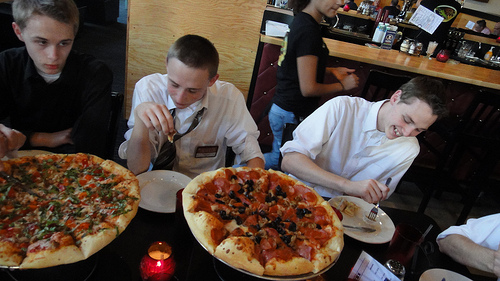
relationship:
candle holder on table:
[138, 241, 176, 278] [1, 170, 348, 272]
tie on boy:
[151, 107, 204, 171] [118, 34, 264, 176]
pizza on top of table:
[0, 149, 140, 269] [1, 161, 468, 279]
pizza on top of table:
[181, 167, 344, 276] [1, 161, 468, 279]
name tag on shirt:
[188, 141, 225, 160] [116, 65, 273, 175]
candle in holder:
[139, 240, 176, 280] [137, 239, 177, 279]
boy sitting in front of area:
[0, 9, 121, 160] [0, 5, 128, 146]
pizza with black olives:
[183, 166, 345, 274] [217, 172, 317, 252]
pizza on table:
[0, 147, 140, 266] [0, 196, 472, 279]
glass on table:
[386, 224, 424, 264] [19, 152, 442, 279]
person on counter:
[232, 0, 360, 170] [331, 45, 497, 82]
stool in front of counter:
[424, 85, 497, 227] [261, 27, 498, 91]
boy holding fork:
[279, 77, 449, 204] [368, 175, 395, 221]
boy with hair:
[279, 77, 449, 204] [164, 33, 219, 83]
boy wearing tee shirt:
[0, 0, 112, 159] [0, 49, 158, 146]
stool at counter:
[416, 90, 500, 226] [321, 38, 500, 90]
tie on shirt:
[150, 100, 213, 178] [119, 89, 252, 192]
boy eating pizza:
[0, 0, 112, 159] [183, 166, 345, 274]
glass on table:
[378, 206, 435, 277] [81, 202, 478, 277]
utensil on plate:
[340, 219, 377, 235] [324, 192, 400, 243]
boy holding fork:
[279, 77, 449, 204] [364, 176, 392, 236]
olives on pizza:
[221, 179, 332, 244] [183, 166, 345, 274]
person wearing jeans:
[232, 0, 360, 170] [261, 107, 291, 173]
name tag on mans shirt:
[194, 146, 218, 159] [115, 70, 267, 178]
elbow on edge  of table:
[433, 212, 472, 269] [57, 149, 437, 269]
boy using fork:
[280, 71, 440, 227] [360, 170, 396, 218]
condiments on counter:
[370, 19, 449, 64] [320, 36, 499, 94]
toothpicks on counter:
[372, 19, 449, 63] [320, 36, 499, 94]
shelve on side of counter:
[300, 0, 498, 67] [320, 30, 497, 96]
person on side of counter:
[258, 6, 361, 163] [320, 30, 497, 96]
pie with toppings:
[15, 147, 137, 274] [2, 149, 124, 248]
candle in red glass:
[139, 240, 176, 280] [136, 242, 186, 278]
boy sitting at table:
[0, 0, 112, 159] [3, 139, 433, 279]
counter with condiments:
[324, 19, 499, 90] [370, 19, 449, 64]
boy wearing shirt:
[0, 0, 112, 159] [0, 47, 115, 165]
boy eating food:
[279, 77, 449, 204] [324, 192, 381, 235]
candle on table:
[110, 202, 185, 278] [34, 95, 456, 273]